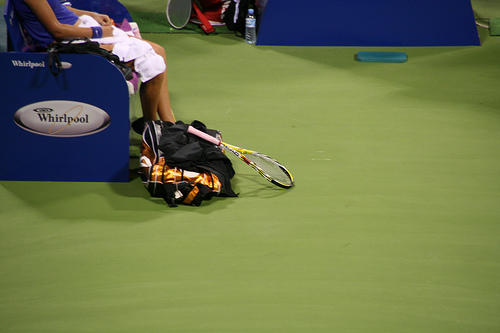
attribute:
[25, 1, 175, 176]
person — sitting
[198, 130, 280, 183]
racket — tennis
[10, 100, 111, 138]
ad — whirpool ad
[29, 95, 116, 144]
letter — black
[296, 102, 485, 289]
floor — green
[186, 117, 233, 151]
handle — pink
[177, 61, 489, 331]
carpeting — green, low nap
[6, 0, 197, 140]
person — sitting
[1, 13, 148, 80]
person — sitting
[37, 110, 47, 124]
letter — black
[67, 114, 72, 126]
letter — black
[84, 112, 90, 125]
letter — black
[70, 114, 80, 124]
letter — black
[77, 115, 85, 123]
letter — black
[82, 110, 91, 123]
letter — black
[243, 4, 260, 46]
bottle — water bottle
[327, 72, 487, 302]
ground — green, smooth, to play on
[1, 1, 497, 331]
floor — green, blue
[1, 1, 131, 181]
bench — end, blue, dark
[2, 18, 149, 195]
bench — blue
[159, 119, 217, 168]
bag — black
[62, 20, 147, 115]
person — sitting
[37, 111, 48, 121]
letter — black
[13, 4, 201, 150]
person — sitting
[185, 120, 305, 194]
racquet — tennis, pink, black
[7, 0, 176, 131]
person — sitting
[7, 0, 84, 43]
shirt — blue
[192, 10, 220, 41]
strap — red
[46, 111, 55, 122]
letter — black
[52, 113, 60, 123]
letter — black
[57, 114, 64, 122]
letter — black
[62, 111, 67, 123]
letter — black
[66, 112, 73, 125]
letter — black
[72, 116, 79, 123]
letter — black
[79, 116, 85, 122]
letter — black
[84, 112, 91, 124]
letter — black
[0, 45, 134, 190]
bench — blue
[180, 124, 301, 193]
racket — black, white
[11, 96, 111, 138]
symbol — whirlpool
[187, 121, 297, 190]
tennis racket — black, white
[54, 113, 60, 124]
letter — black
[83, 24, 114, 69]
wrist band — blue, nike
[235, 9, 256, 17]
lid — blue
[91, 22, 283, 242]
people — thirsty